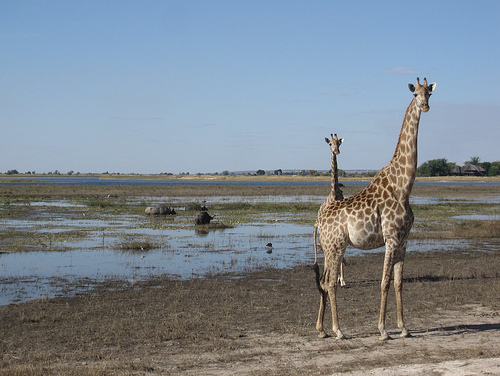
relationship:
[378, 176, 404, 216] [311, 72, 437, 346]
brown spots on giraffe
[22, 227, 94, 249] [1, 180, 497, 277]
weeds growing in swamp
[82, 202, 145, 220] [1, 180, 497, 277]
weeds growing in swamp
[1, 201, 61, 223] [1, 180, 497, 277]
weeds growing in swamp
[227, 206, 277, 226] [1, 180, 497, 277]
weeds growing in swamp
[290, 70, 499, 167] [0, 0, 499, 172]
clouds in sky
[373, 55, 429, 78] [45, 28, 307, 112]
clouds in sky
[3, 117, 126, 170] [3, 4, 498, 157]
clouds in sky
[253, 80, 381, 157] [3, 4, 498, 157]
clouds in sky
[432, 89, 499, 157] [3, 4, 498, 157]
clouds in sky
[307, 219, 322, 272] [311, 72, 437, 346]
tail on giraffe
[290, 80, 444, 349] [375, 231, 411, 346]
giraffe has legs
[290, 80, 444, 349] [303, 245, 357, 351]
giraffe has legs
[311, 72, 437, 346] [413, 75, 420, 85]
giraffe has horn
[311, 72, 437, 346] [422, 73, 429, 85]
giraffe has horn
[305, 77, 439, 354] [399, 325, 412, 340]
giraffe has hoof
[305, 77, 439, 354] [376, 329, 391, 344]
giraffe has hoof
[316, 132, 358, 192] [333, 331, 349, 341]
giraffe has hoof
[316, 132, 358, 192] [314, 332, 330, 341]
giraffe has hoof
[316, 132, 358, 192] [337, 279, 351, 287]
giraffe has hoof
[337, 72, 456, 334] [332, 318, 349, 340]
giraffe has hoof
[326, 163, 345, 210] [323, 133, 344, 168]
giraffe has head